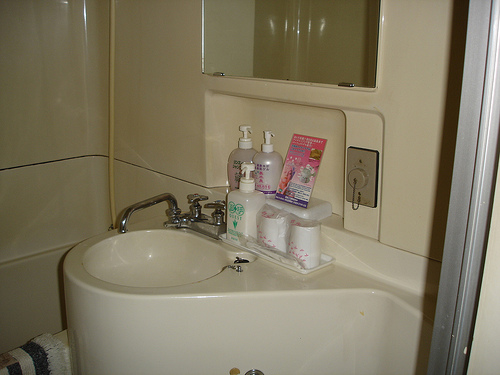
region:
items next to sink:
[177, 93, 369, 285]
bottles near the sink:
[205, 115, 301, 235]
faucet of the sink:
[96, 177, 230, 252]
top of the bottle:
[227, 110, 262, 151]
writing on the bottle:
[218, 205, 258, 235]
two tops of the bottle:
[218, 111, 289, 155]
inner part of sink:
[116, 233, 198, 288]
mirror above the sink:
[206, 5, 358, 70]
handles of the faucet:
[183, 178, 234, 225]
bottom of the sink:
[61, 305, 171, 372]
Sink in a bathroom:
[55, 165, 270, 315]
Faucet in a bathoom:
[105, 202, 190, 236]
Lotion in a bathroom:
[227, 155, 262, 242]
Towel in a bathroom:
[8, 318, 67, 370]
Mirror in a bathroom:
[185, 4, 381, 96]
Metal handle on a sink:
[185, 188, 207, 223]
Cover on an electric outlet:
[343, 164, 375, 212]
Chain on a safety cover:
[348, 185, 363, 210]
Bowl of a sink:
[85, 238, 217, 286]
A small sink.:
[60, 193, 244, 304]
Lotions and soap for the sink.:
[222, 115, 332, 271]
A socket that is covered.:
[342, 143, 379, 210]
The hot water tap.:
[185, 188, 207, 222]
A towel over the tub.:
[2, 340, 65, 374]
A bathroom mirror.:
[207, 3, 385, 88]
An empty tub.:
[10, 226, 72, 353]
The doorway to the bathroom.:
[423, 2, 478, 364]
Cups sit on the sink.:
[261, 205, 328, 269]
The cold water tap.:
[207, 195, 225, 228]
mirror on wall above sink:
[198, 20, 404, 95]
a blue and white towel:
[11, 320, 80, 373]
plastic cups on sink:
[286, 225, 333, 278]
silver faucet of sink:
[98, 188, 190, 240]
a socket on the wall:
[336, 141, 391, 238]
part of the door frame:
[421, 49, 499, 359]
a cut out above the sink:
[205, 95, 370, 198]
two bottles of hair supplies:
[231, 126, 283, 196]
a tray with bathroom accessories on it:
[226, 208, 342, 281]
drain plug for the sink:
[228, 256, 263, 279]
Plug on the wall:
[336, 140, 386, 212]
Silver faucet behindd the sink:
[110, 191, 229, 237]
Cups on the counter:
[289, 216, 324, 272]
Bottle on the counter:
[224, 158, 264, 243]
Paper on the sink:
[275, 126, 331, 211]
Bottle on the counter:
[251, 123, 283, 200]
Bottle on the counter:
[222, 123, 260, 190]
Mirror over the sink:
[172, 1, 406, 95]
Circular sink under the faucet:
[64, 221, 244, 306]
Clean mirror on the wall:
[200, 3, 383, 88]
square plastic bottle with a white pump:
[228, 160, 259, 241]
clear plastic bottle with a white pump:
[228, 125, 255, 188]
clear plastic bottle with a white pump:
[253, 128, 283, 193]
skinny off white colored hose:
[105, 2, 116, 224]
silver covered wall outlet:
[344, 143, 379, 208]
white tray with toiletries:
[220, 231, 336, 273]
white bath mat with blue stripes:
[3, 330, 70, 374]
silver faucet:
[119, 188, 181, 235]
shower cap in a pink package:
[277, 132, 327, 207]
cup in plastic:
[254, 202, 287, 254]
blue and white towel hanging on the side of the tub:
[17, 343, 64, 372]